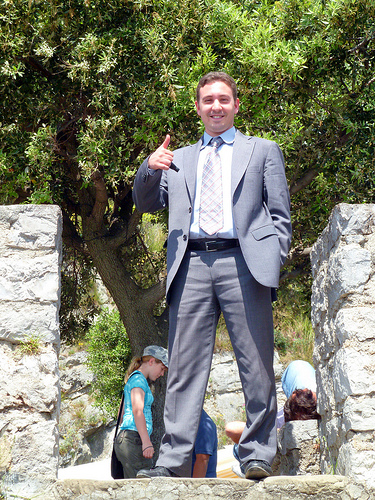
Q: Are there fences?
A: No, there are no fences.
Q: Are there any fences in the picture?
A: No, there are no fences.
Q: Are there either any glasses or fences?
A: No, there are no fences or glasses.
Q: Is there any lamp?
A: No, there are no lamps.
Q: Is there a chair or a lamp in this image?
A: No, there are no lamps or chairs.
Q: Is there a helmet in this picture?
A: No, there are no helmets.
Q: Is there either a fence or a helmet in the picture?
A: No, there are no helmets or fences.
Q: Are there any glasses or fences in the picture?
A: No, there are no fences or glasses.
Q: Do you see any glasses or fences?
A: No, there are no fences or glasses.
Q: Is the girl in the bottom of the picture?
A: Yes, the girl is in the bottom of the image.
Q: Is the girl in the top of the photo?
A: No, the girl is in the bottom of the image.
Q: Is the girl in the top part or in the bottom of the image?
A: The girl is in the bottom of the image.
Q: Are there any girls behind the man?
A: Yes, there is a girl behind the man.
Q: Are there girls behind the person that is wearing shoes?
A: Yes, there is a girl behind the man.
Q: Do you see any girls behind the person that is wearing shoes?
A: Yes, there is a girl behind the man.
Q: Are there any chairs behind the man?
A: No, there is a girl behind the man.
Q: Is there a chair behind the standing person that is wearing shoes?
A: No, there is a girl behind the man.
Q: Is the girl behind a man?
A: Yes, the girl is behind a man.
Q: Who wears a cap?
A: The girl wears a cap.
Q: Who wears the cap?
A: The girl wears a cap.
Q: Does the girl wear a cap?
A: Yes, the girl wears a cap.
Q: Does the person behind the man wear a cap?
A: Yes, the girl wears a cap.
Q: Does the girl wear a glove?
A: No, the girl wears a cap.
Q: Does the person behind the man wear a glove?
A: No, the girl wears a cap.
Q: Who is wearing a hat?
A: The girl is wearing a hat.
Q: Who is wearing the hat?
A: The girl is wearing a hat.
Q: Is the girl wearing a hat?
A: Yes, the girl is wearing a hat.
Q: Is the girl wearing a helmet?
A: No, the girl is wearing a hat.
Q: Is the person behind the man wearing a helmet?
A: No, the girl is wearing a hat.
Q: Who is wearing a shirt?
A: The girl is wearing a shirt.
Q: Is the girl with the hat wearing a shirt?
A: Yes, the girl is wearing a shirt.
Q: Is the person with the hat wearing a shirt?
A: Yes, the girl is wearing a shirt.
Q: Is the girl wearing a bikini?
A: No, the girl is wearing a shirt.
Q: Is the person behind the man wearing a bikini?
A: No, the girl is wearing a shirt.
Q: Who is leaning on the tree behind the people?
A: The girl is leaning on the tree.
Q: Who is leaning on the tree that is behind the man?
A: The girl is leaning on the tree.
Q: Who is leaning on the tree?
A: The girl is leaning on the tree.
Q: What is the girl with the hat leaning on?
A: The girl is leaning on the tree.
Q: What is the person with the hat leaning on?
A: The girl is leaning on the tree.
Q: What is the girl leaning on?
A: The girl is leaning on the tree.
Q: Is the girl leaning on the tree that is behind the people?
A: Yes, the girl is leaning on the tree.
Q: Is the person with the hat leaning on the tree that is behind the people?
A: Yes, the girl is leaning on the tree.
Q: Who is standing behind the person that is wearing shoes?
A: The girl is standing behind the man.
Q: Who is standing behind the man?
A: The girl is standing behind the man.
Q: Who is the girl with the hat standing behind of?
A: The girl is standing behind the man.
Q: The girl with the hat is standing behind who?
A: The girl is standing behind the man.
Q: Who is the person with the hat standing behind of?
A: The girl is standing behind the man.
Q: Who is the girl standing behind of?
A: The girl is standing behind the man.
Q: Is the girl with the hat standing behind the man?
A: Yes, the girl is standing behind the man.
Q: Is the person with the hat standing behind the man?
A: Yes, the girl is standing behind the man.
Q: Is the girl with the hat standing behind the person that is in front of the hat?
A: Yes, the girl is standing behind the man.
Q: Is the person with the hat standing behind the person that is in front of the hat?
A: Yes, the girl is standing behind the man.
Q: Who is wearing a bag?
A: The girl is wearing a bag.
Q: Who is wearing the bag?
A: The girl is wearing a bag.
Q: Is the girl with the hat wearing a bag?
A: Yes, the girl is wearing a bag.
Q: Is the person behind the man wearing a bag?
A: Yes, the girl is wearing a bag.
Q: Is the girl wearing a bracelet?
A: No, the girl is wearing a bag.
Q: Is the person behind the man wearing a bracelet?
A: No, the girl is wearing a bag.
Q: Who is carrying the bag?
A: The girl is carrying the bag.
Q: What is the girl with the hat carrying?
A: The girl is carrying a bag.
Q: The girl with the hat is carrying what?
A: The girl is carrying a bag.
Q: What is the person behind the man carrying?
A: The girl is carrying a bag.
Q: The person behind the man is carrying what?
A: The girl is carrying a bag.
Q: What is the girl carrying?
A: The girl is carrying a bag.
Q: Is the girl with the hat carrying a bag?
A: Yes, the girl is carrying a bag.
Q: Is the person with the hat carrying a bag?
A: Yes, the girl is carrying a bag.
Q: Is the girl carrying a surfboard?
A: No, the girl is carrying a bag.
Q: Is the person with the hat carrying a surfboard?
A: No, the girl is carrying a bag.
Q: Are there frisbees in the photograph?
A: No, there are no frisbees.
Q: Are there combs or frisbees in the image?
A: No, there are no frisbees or combs.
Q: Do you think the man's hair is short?
A: Yes, the hair is short.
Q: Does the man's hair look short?
A: Yes, the hair is short.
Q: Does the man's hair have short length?
A: Yes, the hair is short.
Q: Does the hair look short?
A: Yes, the hair is short.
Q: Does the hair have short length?
A: Yes, the hair is short.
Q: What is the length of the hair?
A: The hair is short.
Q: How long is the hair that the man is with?
A: The hair is short.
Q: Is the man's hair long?
A: No, the hair is short.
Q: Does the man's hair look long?
A: No, the hair is short.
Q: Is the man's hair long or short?
A: The hair is short.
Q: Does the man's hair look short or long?
A: The hair is short.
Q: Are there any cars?
A: No, there are no cars.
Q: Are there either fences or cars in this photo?
A: No, there are no cars or fences.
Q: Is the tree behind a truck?
A: No, the tree is behind the man.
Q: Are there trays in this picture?
A: No, there are no trays.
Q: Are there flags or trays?
A: No, there are no trays or flags.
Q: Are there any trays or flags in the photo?
A: No, there are no trays or flags.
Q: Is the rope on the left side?
A: Yes, the rope is on the left of the image.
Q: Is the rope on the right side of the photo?
A: No, the rope is on the left of the image.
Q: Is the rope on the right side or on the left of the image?
A: The rope is on the left of the image.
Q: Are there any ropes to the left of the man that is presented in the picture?
A: Yes, there is a rope to the left of the man.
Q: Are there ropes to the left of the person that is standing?
A: Yes, there is a rope to the left of the man.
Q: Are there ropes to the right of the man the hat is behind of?
A: No, the rope is to the left of the man.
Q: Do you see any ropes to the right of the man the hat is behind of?
A: No, the rope is to the left of the man.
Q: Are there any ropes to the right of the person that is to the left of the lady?
A: No, the rope is to the left of the man.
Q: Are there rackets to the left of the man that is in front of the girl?
A: No, there is a rope to the left of the man.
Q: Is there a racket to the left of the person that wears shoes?
A: No, there is a rope to the left of the man.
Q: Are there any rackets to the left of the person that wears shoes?
A: No, there is a rope to the left of the man.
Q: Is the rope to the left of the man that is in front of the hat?
A: Yes, the rope is to the left of the man.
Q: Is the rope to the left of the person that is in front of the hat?
A: Yes, the rope is to the left of the man.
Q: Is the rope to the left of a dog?
A: No, the rope is to the left of the man.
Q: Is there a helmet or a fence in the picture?
A: No, there are no fences or helmets.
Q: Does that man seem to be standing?
A: Yes, the man is standing.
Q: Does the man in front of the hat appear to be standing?
A: Yes, the man is standing.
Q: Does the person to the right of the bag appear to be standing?
A: Yes, the man is standing.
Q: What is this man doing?
A: The man is standing.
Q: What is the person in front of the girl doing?
A: The man is standing.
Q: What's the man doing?
A: The man is standing.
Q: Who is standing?
A: The man is standing.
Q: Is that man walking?
A: No, the man is standing.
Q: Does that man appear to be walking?
A: No, the man is standing.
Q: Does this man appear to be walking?
A: No, the man is standing.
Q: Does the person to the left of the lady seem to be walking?
A: No, the man is standing.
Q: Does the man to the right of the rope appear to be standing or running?
A: The man is standing.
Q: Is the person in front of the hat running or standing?
A: The man is standing.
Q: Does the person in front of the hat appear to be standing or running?
A: The man is standing.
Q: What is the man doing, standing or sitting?
A: The man is standing.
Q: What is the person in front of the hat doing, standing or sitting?
A: The man is standing.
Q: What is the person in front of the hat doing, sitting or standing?
A: The man is standing.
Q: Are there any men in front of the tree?
A: Yes, there is a man in front of the tree.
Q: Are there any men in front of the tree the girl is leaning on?
A: Yes, there is a man in front of the tree.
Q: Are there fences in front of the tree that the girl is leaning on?
A: No, there is a man in front of the tree.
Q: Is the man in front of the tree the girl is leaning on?
A: Yes, the man is in front of the tree.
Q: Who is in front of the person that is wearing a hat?
A: The man is in front of the girl.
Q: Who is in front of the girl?
A: The man is in front of the girl.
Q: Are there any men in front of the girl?
A: Yes, there is a man in front of the girl.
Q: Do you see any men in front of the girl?
A: Yes, there is a man in front of the girl.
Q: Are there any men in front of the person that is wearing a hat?
A: Yes, there is a man in front of the girl.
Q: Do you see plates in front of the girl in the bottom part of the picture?
A: No, there is a man in front of the girl.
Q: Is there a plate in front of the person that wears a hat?
A: No, there is a man in front of the girl.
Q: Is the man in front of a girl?
A: Yes, the man is in front of a girl.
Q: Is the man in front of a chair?
A: No, the man is in front of a girl.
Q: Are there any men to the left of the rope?
A: No, the man is to the right of the rope.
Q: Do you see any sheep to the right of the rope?
A: No, there is a man to the right of the rope.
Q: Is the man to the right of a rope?
A: Yes, the man is to the right of a rope.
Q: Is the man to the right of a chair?
A: No, the man is to the right of a rope.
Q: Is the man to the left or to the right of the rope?
A: The man is to the right of the rope.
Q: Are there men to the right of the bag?
A: Yes, there is a man to the right of the bag.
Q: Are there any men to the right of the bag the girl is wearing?
A: Yes, there is a man to the right of the bag.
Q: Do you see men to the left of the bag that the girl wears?
A: No, the man is to the right of the bag.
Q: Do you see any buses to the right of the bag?
A: No, there is a man to the right of the bag.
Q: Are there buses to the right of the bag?
A: No, there is a man to the right of the bag.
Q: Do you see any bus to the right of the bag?
A: No, there is a man to the right of the bag.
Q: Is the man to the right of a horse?
A: No, the man is to the right of the bag.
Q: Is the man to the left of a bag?
A: No, the man is to the right of a bag.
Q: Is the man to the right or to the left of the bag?
A: The man is to the right of the bag.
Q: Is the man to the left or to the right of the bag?
A: The man is to the right of the bag.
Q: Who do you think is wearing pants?
A: The man is wearing pants.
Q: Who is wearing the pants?
A: The man is wearing pants.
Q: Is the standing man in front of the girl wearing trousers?
A: Yes, the man is wearing trousers.